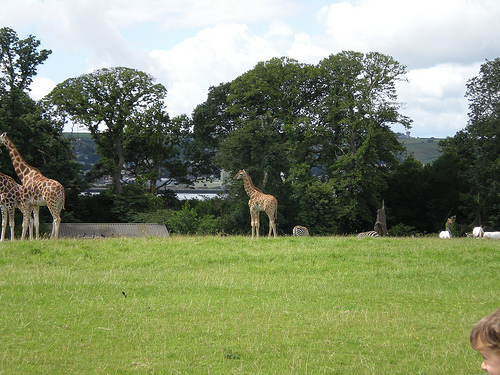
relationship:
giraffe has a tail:
[233, 168, 280, 237] [274, 196, 279, 224]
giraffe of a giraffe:
[233, 168, 279, 239] [1, 130, 72, 245]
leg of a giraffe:
[17, 206, 29, 242] [1, 130, 72, 245]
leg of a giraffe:
[43, 215, 60, 241] [1, 130, 72, 245]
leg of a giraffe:
[249, 212, 257, 239] [1, 130, 72, 245]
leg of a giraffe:
[267, 213, 279, 240] [1, 130, 72, 245]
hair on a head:
[469, 310, 500, 358] [464, 306, 498, 374]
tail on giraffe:
[274, 198, 279, 224] [233, 168, 279, 239]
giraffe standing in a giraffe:
[233, 168, 280, 237] [0, 128, 67, 243]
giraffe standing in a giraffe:
[233, 168, 280, 237] [0, 172, 34, 239]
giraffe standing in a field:
[233, 168, 280, 237] [1, 232, 498, 369]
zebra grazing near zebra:
[357, 230, 381, 239] [357, 230, 381, 239]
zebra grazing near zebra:
[357, 230, 381, 239] [291, 226, 309, 239]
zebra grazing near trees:
[357, 230, 381, 239] [460, 56, 499, 235]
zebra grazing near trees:
[357, 230, 381, 239] [314, 51, 411, 241]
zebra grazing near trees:
[357, 230, 381, 239] [38, 66, 173, 222]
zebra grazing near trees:
[357, 230, 381, 239] [170, 76, 250, 238]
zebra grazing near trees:
[357, 230, 381, 239] [391, 136, 448, 238]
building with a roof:
[1, 129, 271, 224] [56, 129, 219, 179]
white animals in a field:
[436, 224, 498, 241] [1, 232, 498, 369]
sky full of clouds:
[18, 27, 491, 129] [404, 64, 474, 101]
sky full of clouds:
[18, 27, 491, 129] [151, 26, 270, 72]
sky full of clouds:
[18, 27, 491, 129] [289, 27, 327, 62]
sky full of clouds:
[18, 27, 491, 129] [29, 77, 51, 99]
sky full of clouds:
[18, 27, 491, 129] [435, 105, 464, 135]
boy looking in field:
[446, 304, 497, 372] [298, 235, 428, 330]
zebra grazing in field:
[352, 224, 382, 245] [1, 232, 498, 369]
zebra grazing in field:
[291, 226, 309, 239] [1, 232, 498, 369]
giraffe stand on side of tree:
[1, 171, 35, 241] [204, 110, 299, 237]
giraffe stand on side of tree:
[0, 128, 67, 243] [204, 110, 299, 237]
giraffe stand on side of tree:
[233, 168, 279, 239] [204, 110, 299, 237]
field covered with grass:
[1, 232, 498, 369] [0, 235, 499, 374]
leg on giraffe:
[10, 205, 60, 254] [0, 132, 65, 241]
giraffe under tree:
[233, 168, 279, 239] [207, 66, 333, 164]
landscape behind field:
[149, 169, 480, 359] [41, 107, 492, 168]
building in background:
[71, 157, 338, 201] [98, 122, 352, 259]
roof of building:
[77, 157, 229, 192] [71, 157, 338, 201]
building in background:
[71, 157, 338, 201] [150, 150, 294, 205]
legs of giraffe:
[18, 202, 69, 243] [233, 168, 280, 237]